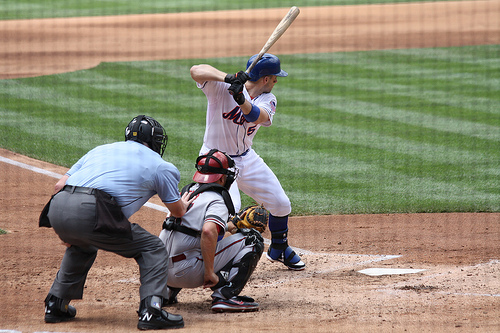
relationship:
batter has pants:
[190, 51, 310, 274] [196, 148, 293, 217]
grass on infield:
[317, 60, 499, 194] [3, 6, 498, 239]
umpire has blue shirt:
[38, 114, 186, 329] [61, 141, 183, 221]